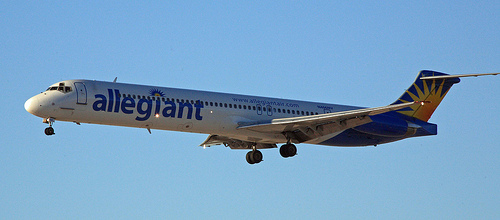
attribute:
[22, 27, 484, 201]
airplane — sky , air, one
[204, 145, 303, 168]
wheel — down , black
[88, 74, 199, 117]
logo — blue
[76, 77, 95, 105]
door — white, exit, gray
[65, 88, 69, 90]
window — tiny, row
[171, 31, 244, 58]
sky — blue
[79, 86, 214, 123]
print — blue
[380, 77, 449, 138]
lego — blue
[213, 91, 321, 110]
address — printed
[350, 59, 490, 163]
tail — plane